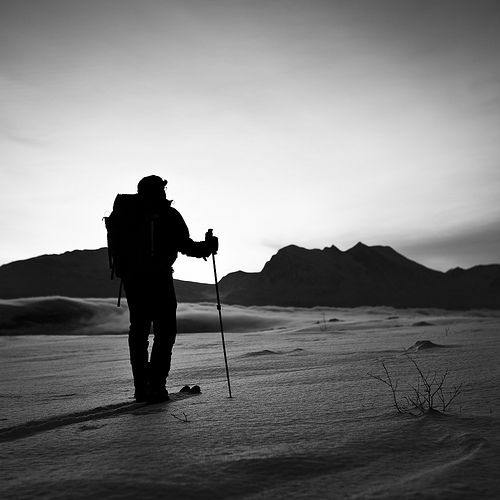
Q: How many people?
A: One.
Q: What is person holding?
A: Pole.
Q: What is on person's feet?
A: Skis.